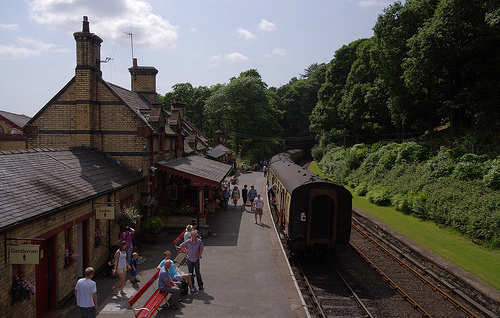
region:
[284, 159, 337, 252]
old brown train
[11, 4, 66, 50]
white cloud in blue sky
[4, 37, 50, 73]
white cloud in blue sky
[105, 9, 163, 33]
white cloud in blue sky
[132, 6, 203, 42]
white cloud in blue sky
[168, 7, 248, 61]
white cloud in blue sky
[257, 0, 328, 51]
white cloud in blue sky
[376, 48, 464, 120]
green leaves on trees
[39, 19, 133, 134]
brown chimney in building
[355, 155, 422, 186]
green bushes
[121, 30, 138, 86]
a flagpole on top of the building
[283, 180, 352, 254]
the back end of the train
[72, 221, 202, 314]
people standing and sitting around the bench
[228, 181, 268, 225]
the people waiting to get on the train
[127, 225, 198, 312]
a line of benches sitting on the platform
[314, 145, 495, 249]
a line of leafy bushes next to the tracks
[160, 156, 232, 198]
a covering over part of the platform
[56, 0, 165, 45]
a big cloud floating in the sky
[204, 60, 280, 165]
a big leafy tree at the end of the track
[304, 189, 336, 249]
a door at the end of the train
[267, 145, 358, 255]
a train sitting on the track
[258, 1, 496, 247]
a row of leafy trees and bushes next to the tracks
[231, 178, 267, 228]
people waiting to get on the train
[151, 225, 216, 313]
people waiting around on the benches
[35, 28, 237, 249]
a big building next to the platform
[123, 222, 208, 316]
a row of trees next to the building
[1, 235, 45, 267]
a sign for the man's bathroom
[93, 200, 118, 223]
a sign for the woman's bathroom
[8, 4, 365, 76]
the sky above with some clouds floating by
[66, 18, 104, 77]
a little tower on top of the building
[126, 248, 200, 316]
Two people sitting on red bench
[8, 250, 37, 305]
Window sill consisting of flowers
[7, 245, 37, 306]
Flowers in window sill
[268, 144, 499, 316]
Train on tracks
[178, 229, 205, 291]
Standing man wearing purple shirt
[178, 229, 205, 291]
Standing man wearing blue jeans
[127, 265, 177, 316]
Red bench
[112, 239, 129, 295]
Woman wearing white tank top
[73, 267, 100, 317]
Man wearing white t-shirt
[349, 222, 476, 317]
Brown train tracks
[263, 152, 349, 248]
Train waiting at the station platform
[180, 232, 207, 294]
Man standing with his hands on his hips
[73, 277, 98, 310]
White shirt of man walking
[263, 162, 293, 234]
Right side of train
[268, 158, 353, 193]
Top of passenger train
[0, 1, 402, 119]
White clouds in blue sky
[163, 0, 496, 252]
Tall trees on the side of train station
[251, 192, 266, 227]
Man walking down the platform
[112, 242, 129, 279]
woman wearing a white tank top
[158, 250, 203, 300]
Man sitting and wearing a blue top